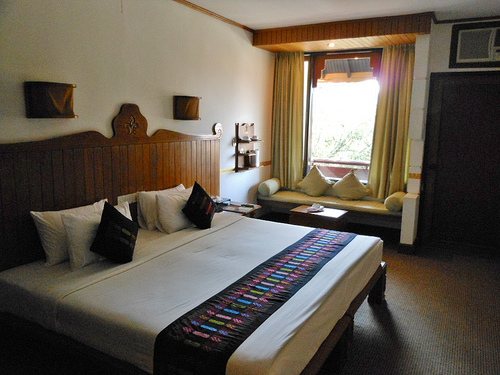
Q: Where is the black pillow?
A: On the bed.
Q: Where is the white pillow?
A: On the bed.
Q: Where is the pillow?
A: On the bed.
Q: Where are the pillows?
A: On the bed.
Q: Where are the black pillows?
A: On the bed.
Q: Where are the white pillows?
A: On the bed.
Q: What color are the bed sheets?
A: White.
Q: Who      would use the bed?
A: A sleepy person.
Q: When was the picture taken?
A: Daytime.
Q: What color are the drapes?
A: Gold.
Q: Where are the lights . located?
A: On the wall.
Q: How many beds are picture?
A: One.